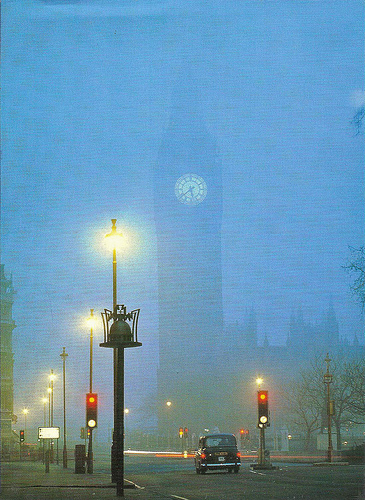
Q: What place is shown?
A: It is a city.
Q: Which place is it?
A: It is a city.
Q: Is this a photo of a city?
A: Yes, it is showing a city.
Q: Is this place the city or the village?
A: It is the city.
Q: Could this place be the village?
A: No, it is the city.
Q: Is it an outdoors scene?
A: Yes, it is outdoors.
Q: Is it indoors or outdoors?
A: It is outdoors.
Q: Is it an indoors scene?
A: No, it is outdoors.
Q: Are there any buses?
A: No, there are no buses.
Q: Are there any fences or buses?
A: No, there are no buses or fences.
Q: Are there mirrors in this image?
A: No, there are no mirrors.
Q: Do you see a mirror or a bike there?
A: No, there are no mirrors or bikes.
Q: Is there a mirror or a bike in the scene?
A: No, there are no mirrors or bikes.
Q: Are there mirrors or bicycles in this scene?
A: No, there are no mirrors or bicycles.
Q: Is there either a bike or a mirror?
A: No, there are no mirrors or bikes.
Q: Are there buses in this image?
A: No, there are no buses.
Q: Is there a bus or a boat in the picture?
A: No, there are no buses or boats.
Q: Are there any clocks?
A: Yes, there is a clock.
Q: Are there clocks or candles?
A: Yes, there is a clock.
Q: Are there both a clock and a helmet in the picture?
A: No, there is a clock but no helmets.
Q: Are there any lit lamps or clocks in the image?
A: Yes, there is a lit clock.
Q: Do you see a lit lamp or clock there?
A: Yes, there is a lit clock.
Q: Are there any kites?
A: No, there are no kites.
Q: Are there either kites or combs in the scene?
A: No, there are no kites or combs.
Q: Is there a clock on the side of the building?
A: Yes, there is a clock on the side of the building.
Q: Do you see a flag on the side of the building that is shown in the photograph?
A: No, there is a clock on the side of the building.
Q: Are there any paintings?
A: No, there are no paintings.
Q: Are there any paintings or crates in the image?
A: No, there are no paintings or crates.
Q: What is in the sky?
A: The fog is in the sky.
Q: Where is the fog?
A: The fog is in the sky.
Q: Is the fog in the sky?
A: Yes, the fog is in the sky.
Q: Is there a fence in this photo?
A: No, there are no fences.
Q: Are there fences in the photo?
A: No, there are no fences.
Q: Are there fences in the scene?
A: No, there are no fences.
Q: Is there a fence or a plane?
A: No, there are no fences or airplanes.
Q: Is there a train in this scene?
A: No, there are no trains.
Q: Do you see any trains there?
A: No, there are no trains.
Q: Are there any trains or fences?
A: No, there are no trains or fences.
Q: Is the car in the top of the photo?
A: No, the car is in the bottom of the image.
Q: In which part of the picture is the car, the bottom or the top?
A: The car is in the bottom of the image.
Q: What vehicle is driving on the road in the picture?
A: The vehicle is a car.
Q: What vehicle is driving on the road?
A: The vehicle is a car.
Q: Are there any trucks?
A: No, there are no trucks.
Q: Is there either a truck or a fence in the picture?
A: No, there are no trucks or fences.